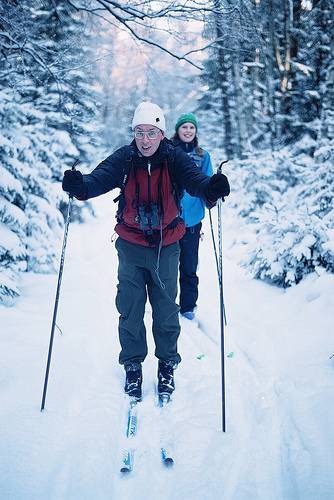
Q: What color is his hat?
A: White.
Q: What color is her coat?
A: Blue.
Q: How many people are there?
A: Two.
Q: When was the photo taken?
A: Day time.